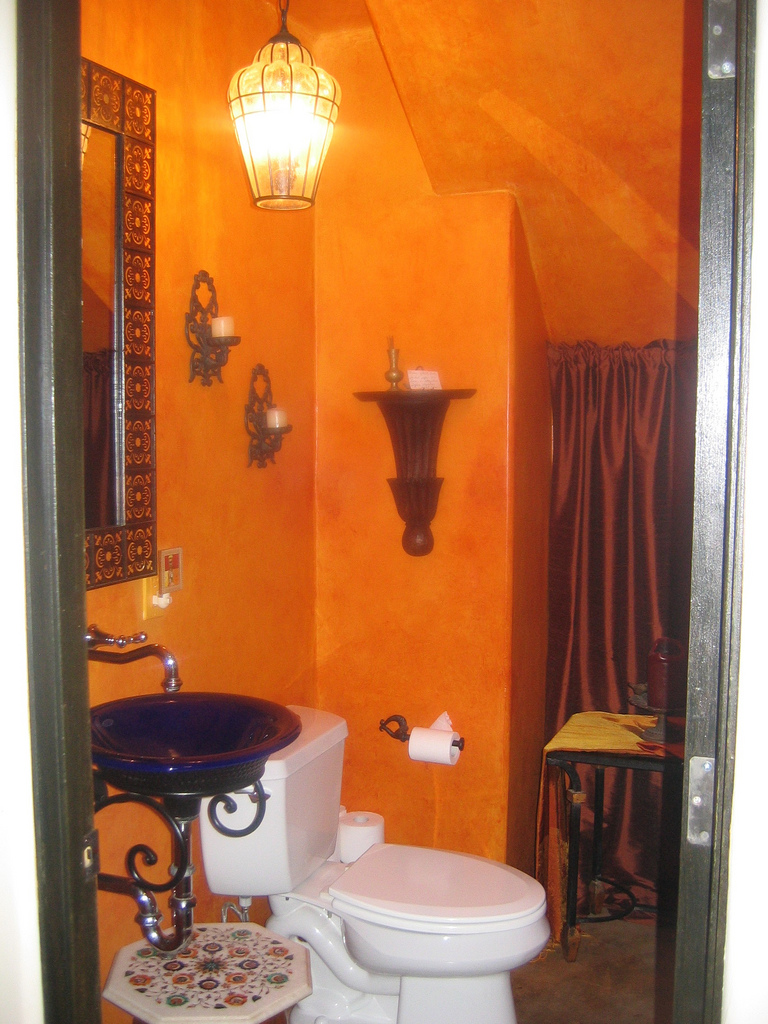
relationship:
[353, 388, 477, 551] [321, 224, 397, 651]
wooden shelf on a wall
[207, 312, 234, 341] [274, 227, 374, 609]
candle on wall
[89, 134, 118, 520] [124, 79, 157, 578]
mirror with patterned frame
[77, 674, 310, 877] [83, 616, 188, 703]
sink with faucet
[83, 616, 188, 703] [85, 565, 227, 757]
faucet in wall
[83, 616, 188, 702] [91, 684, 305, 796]
faucet above sink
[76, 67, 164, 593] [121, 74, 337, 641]
mirror frame on wall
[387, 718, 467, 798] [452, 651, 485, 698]
toilet paper on wall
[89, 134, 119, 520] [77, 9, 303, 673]
mirror on wall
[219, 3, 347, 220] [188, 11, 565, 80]
light on ceiling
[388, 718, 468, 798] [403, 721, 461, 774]
toilet in roll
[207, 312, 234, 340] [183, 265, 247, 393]
candle in candle holder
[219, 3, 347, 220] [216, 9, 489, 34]
light on ceiling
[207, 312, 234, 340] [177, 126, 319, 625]
candle on wall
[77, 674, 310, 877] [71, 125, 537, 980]
sink on wall